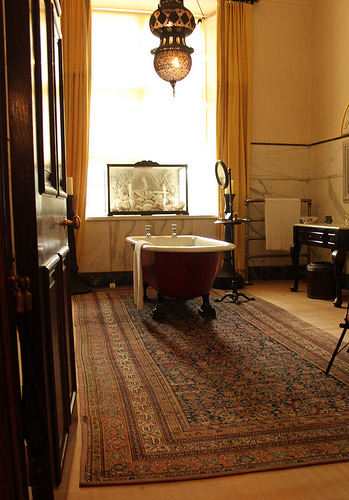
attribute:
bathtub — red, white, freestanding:
[127, 234, 236, 328]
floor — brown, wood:
[64, 276, 348, 491]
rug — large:
[60, 278, 348, 490]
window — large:
[79, 9, 212, 226]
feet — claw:
[143, 294, 220, 329]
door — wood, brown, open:
[1, 3, 93, 498]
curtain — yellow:
[58, 0, 91, 274]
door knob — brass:
[54, 204, 90, 235]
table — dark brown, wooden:
[283, 204, 348, 309]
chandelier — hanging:
[112, 1, 234, 112]